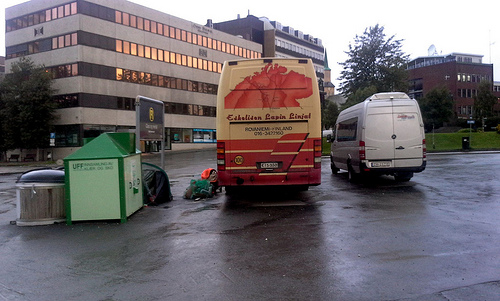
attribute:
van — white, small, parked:
[331, 88, 427, 176]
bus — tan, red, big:
[220, 46, 326, 204]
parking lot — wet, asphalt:
[8, 150, 500, 301]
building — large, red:
[0, 1, 264, 148]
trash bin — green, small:
[64, 132, 148, 221]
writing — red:
[225, 112, 308, 134]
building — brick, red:
[392, 50, 495, 133]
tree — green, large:
[4, 60, 58, 156]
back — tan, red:
[219, 62, 319, 184]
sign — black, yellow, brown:
[139, 103, 162, 138]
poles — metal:
[133, 97, 170, 171]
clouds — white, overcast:
[2, 0, 496, 76]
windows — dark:
[333, 116, 357, 144]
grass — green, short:
[322, 124, 493, 156]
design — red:
[225, 68, 309, 110]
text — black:
[243, 125, 296, 137]